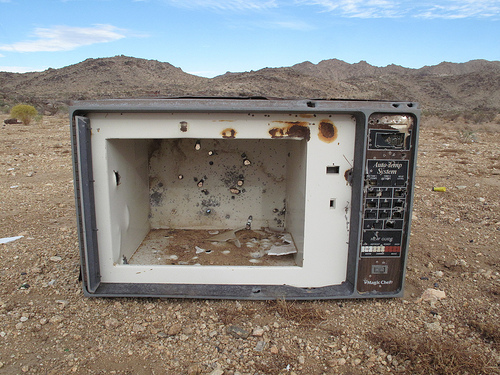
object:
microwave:
[69, 92, 425, 305]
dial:
[366, 125, 415, 153]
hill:
[1, 50, 500, 128]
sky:
[1, 2, 499, 76]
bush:
[6, 102, 42, 130]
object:
[430, 184, 447, 193]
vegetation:
[357, 299, 499, 375]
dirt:
[0, 114, 500, 374]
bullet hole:
[192, 175, 209, 192]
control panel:
[351, 106, 424, 298]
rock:
[100, 314, 124, 334]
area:
[316, 115, 344, 147]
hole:
[317, 121, 336, 140]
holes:
[364, 198, 380, 212]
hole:
[208, 150, 215, 157]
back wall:
[147, 137, 292, 234]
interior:
[105, 134, 311, 270]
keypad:
[362, 158, 408, 246]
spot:
[286, 124, 313, 143]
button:
[378, 198, 393, 210]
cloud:
[0, 20, 121, 57]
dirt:
[148, 227, 301, 267]